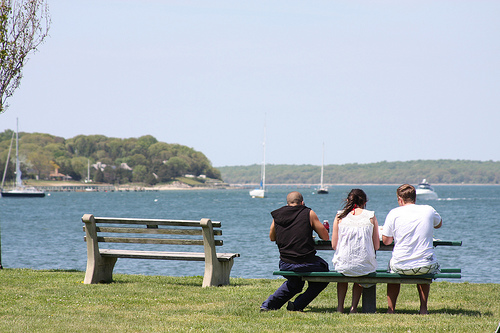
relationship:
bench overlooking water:
[75, 210, 241, 292] [0, 178, 499, 280]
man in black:
[263, 183, 334, 310] [269, 205, 317, 260]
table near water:
[269, 229, 464, 314] [0, 178, 499, 280]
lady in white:
[328, 184, 384, 279] [343, 225, 363, 256]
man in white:
[263, 183, 334, 310] [343, 225, 363, 256]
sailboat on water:
[240, 138, 271, 205] [0, 178, 499, 280]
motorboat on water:
[406, 173, 442, 207] [0, 178, 499, 280]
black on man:
[269, 205, 317, 260] [263, 183, 334, 310]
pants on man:
[271, 259, 326, 308] [263, 183, 334, 310]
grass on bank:
[118, 290, 165, 320] [1, 268, 200, 330]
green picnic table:
[451, 241, 461, 248] [269, 229, 464, 314]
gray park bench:
[212, 268, 228, 280] [75, 210, 241, 292]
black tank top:
[269, 205, 317, 260] [272, 207, 313, 256]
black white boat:
[269, 205, 317, 260] [3, 117, 47, 201]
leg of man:
[267, 270, 294, 313] [263, 183, 334, 310]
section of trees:
[145, 162, 168, 187] [87, 135, 199, 182]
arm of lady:
[328, 210, 342, 247] [326, 187, 381, 315]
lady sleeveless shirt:
[326, 187, 381, 315] [336, 207, 377, 273]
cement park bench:
[203, 262, 235, 276] [75, 210, 241, 292]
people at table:
[267, 173, 432, 279] [269, 229, 464, 314]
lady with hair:
[326, 187, 381, 315] [344, 195, 356, 214]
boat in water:
[3, 117, 47, 201] [8, 214, 73, 258]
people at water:
[267, 173, 432, 279] [8, 214, 73, 258]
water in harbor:
[8, 214, 73, 258] [47, 181, 262, 234]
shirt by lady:
[336, 207, 377, 273] [326, 187, 381, 315]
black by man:
[269, 205, 317, 260] [263, 183, 334, 310]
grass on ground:
[118, 290, 165, 320] [104, 287, 200, 317]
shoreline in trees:
[111, 176, 228, 192] [87, 135, 199, 182]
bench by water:
[75, 210, 241, 292] [8, 214, 73, 258]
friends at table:
[328, 176, 450, 265] [269, 229, 464, 314]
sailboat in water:
[240, 138, 271, 205] [8, 214, 73, 258]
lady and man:
[326, 187, 381, 315] [263, 183, 334, 310]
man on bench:
[263, 183, 334, 310] [75, 210, 241, 292]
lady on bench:
[326, 187, 381, 315] [75, 210, 241, 292]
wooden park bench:
[168, 228, 192, 235] [75, 210, 241, 292]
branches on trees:
[30, 26, 50, 51] [87, 135, 199, 182]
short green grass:
[161, 281, 180, 300] [118, 290, 165, 320]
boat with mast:
[3, 117, 47, 201] [7, 118, 27, 182]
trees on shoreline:
[87, 135, 199, 182] [111, 176, 228, 192]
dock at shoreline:
[54, 180, 165, 194] [111, 176, 228, 192]